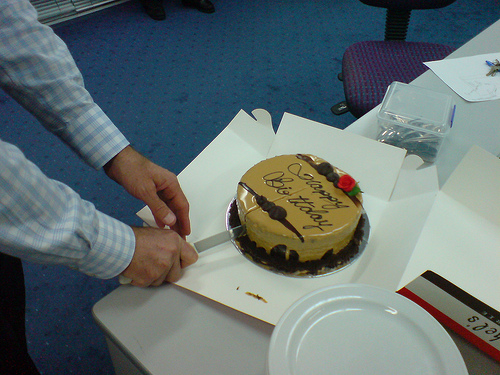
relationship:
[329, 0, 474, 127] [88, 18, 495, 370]
chair next to desk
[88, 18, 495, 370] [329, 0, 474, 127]
desk next to chair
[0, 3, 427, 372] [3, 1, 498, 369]
carpet on floor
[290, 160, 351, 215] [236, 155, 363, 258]
happy on cake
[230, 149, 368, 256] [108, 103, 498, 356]
cake on box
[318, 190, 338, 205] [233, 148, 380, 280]
letter on cake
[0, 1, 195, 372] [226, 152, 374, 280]
person cutting a cake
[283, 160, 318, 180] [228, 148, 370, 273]
letter on cake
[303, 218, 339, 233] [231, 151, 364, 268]
black letter on cake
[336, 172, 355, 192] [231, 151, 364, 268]
rose on cake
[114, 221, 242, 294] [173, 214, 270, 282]
hand holding knife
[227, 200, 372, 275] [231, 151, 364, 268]
base of cake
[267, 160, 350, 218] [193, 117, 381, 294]
lettering on cake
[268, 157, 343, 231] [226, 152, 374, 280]
letter on cake